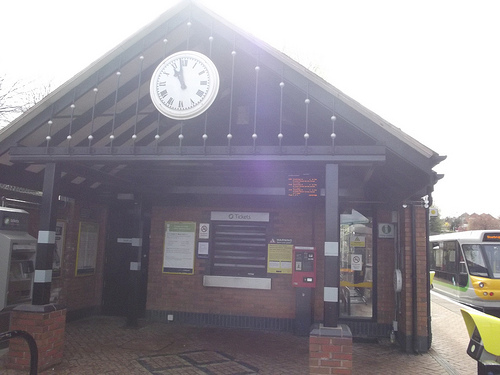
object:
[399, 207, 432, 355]
brick pillar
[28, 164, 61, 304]
poles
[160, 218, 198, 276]
sign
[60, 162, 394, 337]
wall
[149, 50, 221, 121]
clock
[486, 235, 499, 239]
sign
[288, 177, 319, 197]
sign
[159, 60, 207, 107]
roman numeral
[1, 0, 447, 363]
bus terminal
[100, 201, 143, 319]
door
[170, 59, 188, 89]
dial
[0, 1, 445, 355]
building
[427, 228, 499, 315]
train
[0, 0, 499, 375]
railway station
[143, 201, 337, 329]
counter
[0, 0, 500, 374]
colorful kite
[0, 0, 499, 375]
platform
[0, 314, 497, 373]
floor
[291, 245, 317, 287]
machine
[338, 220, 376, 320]
glass door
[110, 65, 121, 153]
metal bar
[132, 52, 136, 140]
metal bar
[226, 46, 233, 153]
metal bar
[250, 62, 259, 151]
metal bar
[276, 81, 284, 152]
metal bar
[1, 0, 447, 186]
roof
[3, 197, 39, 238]
window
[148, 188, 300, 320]
board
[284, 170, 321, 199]
screen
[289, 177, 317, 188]
words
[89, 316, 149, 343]
doorway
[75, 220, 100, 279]
sign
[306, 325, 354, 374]
bricks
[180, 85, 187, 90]
circle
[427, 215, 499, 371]
station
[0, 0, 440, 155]
bars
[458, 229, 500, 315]
head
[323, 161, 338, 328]
bar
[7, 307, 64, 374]
brick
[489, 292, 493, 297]
bumper